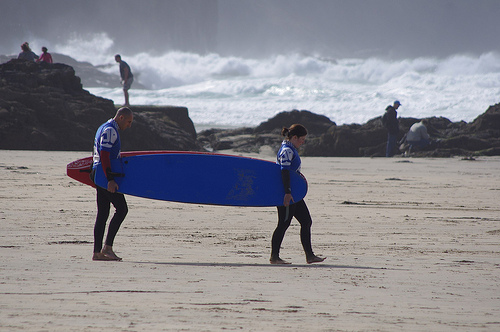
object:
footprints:
[175, 300, 304, 313]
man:
[90, 106, 133, 261]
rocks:
[302, 102, 500, 157]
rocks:
[117, 105, 211, 153]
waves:
[341, 196, 426, 208]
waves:
[452, 260, 474, 263]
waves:
[382, 174, 406, 177]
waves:
[395, 160, 413, 163]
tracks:
[48, 240, 94, 244]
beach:
[0, 150, 497, 332]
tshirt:
[92, 118, 121, 171]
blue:
[98, 127, 102, 136]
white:
[100, 127, 117, 148]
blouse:
[36, 52, 53, 63]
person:
[17, 42, 39, 63]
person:
[36, 46, 53, 63]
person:
[114, 54, 134, 107]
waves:
[221, 121, 314, 156]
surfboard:
[65, 151, 308, 207]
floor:
[0, 150, 500, 332]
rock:
[0, 58, 211, 152]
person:
[270, 123, 328, 264]